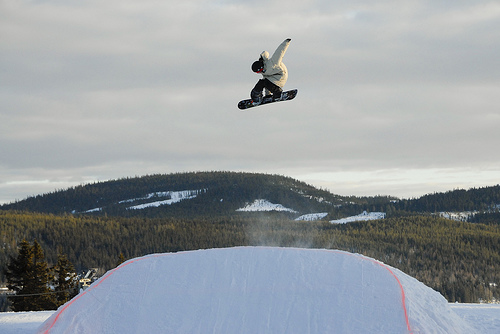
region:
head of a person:
[248, 56, 268, 81]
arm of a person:
[268, 31, 292, 72]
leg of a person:
[240, 72, 267, 110]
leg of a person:
[265, 77, 291, 95]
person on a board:
[220, 82, 297, 124]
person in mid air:
[223, 11, 323, 118]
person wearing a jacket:
[215, 11, 337, 126]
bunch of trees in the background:
[28, 199, 476, 275]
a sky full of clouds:
[35, 36, 165, 112]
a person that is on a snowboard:
[214, 19, 311, 161]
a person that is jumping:
[228, 18, 300, 123]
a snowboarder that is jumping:
[194, 27, 316, 121]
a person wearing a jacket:
[185, 4, 315, 139]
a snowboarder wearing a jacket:
[234, 36, 279, 104]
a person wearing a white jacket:
[253, 32, 315, 129]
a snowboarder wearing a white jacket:
[237, 26, 317, 136]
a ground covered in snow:
[169, 261, 275, 326]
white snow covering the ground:
[210, 275, 339, 332]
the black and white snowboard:
[237, 88, 296, 108]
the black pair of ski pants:
[250, 78, 278, 98]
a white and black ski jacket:
[264, 40, 291, 87]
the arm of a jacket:
[270, 39, 288, 59]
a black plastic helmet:
[252, 61, 264, 71]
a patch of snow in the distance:
[121, 186, 201, 212]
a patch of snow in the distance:
[236, 193, 294, 215]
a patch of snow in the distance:
[294, 209, 328, 223]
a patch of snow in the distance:
[332, 208, 386, 226]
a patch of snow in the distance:
[431, 207, 476, 219]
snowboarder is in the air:
[242, 41, 306, 136]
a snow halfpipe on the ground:
[56, 223, 418, 325]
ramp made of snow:
[105, 232, 440, 329]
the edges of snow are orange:
[20, 208, 429, 331]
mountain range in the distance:
[0, 170, 490, 286]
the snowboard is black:
[231, 80, 311, 113]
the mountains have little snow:
[4, 180, 472, 268]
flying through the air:
[207, 28, 317, 140]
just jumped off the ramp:
[204, 20, 309, 320]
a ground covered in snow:
[117, 254, 249, 321]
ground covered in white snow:
[207, 261, 354, 332]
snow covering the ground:
[157, 251, 319, 330]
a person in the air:
[232, 41, 317, 129]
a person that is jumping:
[224, 31, 328, 131]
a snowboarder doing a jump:
[215, 32, 335, 143]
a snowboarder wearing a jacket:
[226, 19, 287, 131]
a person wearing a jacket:
[237, 28, 314, 140]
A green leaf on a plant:
[87, 230, 88, 231]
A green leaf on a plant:
[107, 226, 109, 227]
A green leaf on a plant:
[13, 221, 14, 222]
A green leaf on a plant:
[483, 252, 485, 253]